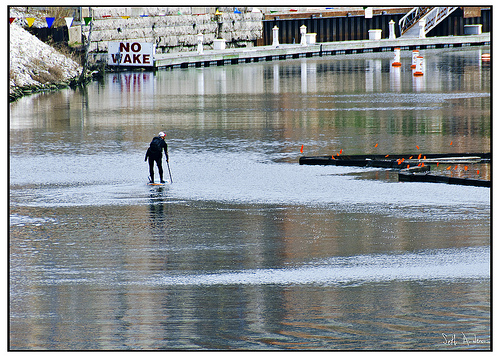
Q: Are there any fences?
A: No, there are no fences.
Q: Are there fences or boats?
A: No, there are no fences or boats.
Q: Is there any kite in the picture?
A: No, there are no kites.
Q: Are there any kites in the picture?
A: No, there are no kites.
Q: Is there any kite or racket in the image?
A: No, there are no kites or rackets.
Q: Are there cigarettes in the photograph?
A: No, there are no cigarettes.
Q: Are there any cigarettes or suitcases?
A: No, there are no cigarettes or suitcases.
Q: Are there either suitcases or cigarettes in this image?
A: No, there are no cigarettes or suitcases.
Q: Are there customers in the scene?
A: No, there are no customers.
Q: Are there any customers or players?
A: No, there are no customers or players.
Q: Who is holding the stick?
A: The man is holding the stick.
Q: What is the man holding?
A: The man is holding the stick.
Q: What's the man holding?
A: The man is holding the stick.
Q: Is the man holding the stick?
A: Yes, the man is holding the stick.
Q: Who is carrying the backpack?
A: The man is carrying the backpack.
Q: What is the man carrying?
A: The man is carrying a backpack.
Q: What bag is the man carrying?
A: The man is carrying a backpack.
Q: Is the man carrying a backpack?
A: Yes, the man is carrying a backpack.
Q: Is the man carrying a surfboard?
A: No, the man is carrying a backpack.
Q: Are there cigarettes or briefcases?
A: No, there are no cigarettes or briefcases.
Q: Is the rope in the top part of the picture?
A: Yes, the rope is in the top of the image.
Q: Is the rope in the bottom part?
A: No, the rope is in the top of the image.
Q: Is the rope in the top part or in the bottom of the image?
A: The rope is in the top of the image.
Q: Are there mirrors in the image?
A: No, there are no mirrors.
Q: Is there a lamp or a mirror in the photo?
A: No, there are no mirrors or lamps.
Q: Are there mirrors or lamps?
A: No, there are no mirrors or lamps.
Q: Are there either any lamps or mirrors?
A: No, there are no mirrors or lamps.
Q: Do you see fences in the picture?
A: No, there are no fences.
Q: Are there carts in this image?
A: No, there are no carts.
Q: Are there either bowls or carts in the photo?
A: No, there are no carts or bowls.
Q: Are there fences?
A: No, there are no fences.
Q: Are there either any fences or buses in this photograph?
A: No, there are no fences or buses.